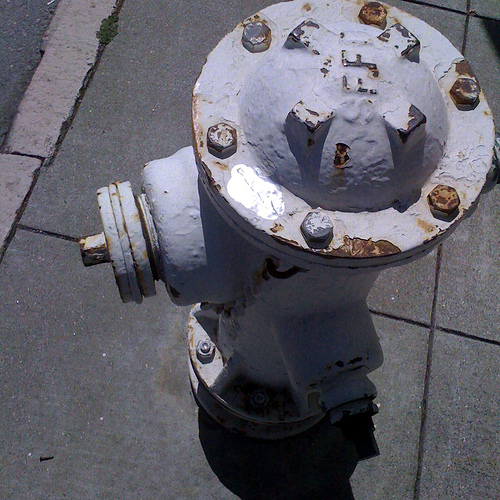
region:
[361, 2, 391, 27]
hex bolt on fire hydrant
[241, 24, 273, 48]
hex bolt on fire hydrant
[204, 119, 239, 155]
hex bolt on fire hydrant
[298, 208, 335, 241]
hex bolt on fire hydrant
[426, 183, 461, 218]
hex bolt on fire hydrant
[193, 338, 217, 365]
hex bolt on fire hydrant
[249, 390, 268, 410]
hex bolt on fire hydrant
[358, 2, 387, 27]
rust colored hex bolt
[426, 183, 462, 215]
rust colored hex bolt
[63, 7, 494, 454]
A grey water hydrant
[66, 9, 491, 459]
A grey water hydrant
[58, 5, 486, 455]
A grey water hydrant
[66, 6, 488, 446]
A grey water hydrant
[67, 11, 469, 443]
A grey water hydrant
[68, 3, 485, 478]
A grey water hydrant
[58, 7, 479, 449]
A grey water hydrant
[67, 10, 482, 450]
A grey water hydrant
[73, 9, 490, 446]
A grey water hydrant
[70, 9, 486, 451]
A grey water hydrant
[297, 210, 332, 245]
hex bolt on fire hydrant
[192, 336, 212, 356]
hex bolt on fire hydrant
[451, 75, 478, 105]
hex bolt on fire hydrant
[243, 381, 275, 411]
hex bolt on fire hydrant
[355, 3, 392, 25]
hex bolt on fire hydrant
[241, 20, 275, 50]
hex bolt on fire hydrant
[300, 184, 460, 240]
hex bolts on fire hydrant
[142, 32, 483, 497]
rusty metal fire hydrant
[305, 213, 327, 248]
rusted bolt on top of hydrant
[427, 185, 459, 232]
rusted bolt on top of hydrant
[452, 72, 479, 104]
rusted bolt on top of hydrant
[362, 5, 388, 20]
rusted bolt on top of hydrant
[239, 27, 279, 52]
rusted bolt on top of hydrant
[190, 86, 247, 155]
rusted bolt on top of hydrant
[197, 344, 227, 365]
rusted bolt on top of hydrant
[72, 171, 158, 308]
rusted cap on top of hydrant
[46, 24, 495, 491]
concrete sidewalk below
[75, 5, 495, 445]
top view of fire hydrant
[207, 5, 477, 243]
bolts in a circle on top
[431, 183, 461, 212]
rusted top of metal bolt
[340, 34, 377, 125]
raised letters on hydrant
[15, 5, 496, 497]
surface of cement sidewalk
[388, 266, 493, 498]
intersecting lines on cement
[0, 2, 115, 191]
curb on edge of sidewalk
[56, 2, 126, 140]
weeds in sidewalk curb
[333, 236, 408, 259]
peeled paint on metal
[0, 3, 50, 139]
asphalt surface of street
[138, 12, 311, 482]
white fire hydrant on the sidewalk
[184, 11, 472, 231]
rust on top of the fire hydrant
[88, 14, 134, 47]
grass growing through the cracks of the side walk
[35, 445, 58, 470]
one nail on the sidewalk near the fire hydrant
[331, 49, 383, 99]
the letters ff on top of the fire hydrant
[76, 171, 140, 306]
rust on the side of the fire hydrant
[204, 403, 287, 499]
shadow from the fire hydrant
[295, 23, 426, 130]
paint chipping from fire hydrant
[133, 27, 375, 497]
rusted white fire hydrant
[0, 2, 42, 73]
road near the sidewalk